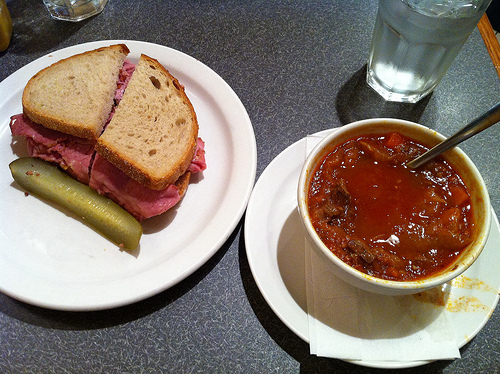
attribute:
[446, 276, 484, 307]
chili — spilled